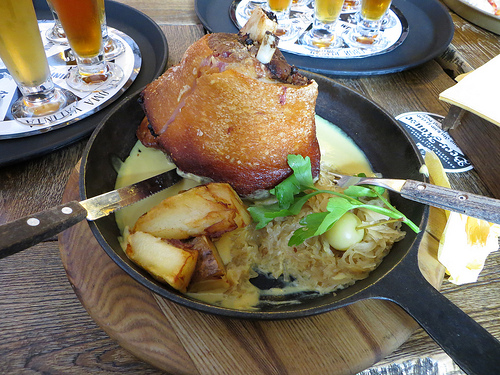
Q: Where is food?
A: In a frying pan.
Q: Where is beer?
A: In glasses.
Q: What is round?
A: Plates.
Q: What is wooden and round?
A: A cooking board.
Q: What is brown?
A: Table.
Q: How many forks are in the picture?
A: One.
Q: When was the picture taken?
A: Daytime.